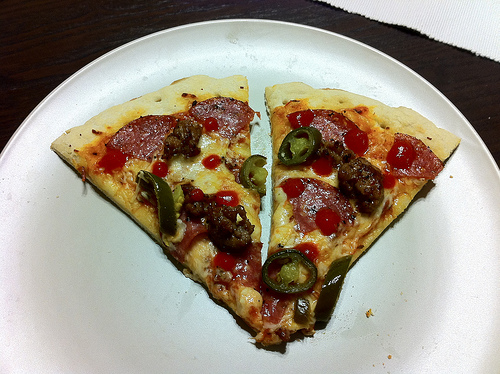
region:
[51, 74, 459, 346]
two slices of pizza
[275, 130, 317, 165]
a jalpeno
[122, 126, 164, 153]
red pepperoni on the pizza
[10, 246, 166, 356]
the pizza pan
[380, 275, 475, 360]
the pizza pan is grey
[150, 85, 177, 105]
the crust on the pizza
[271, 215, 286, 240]
the cheese is yellow on the pizza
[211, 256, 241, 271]
pepperoni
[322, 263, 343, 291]
a green pepper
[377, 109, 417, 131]
the crust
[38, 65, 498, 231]
a plate with two pieces of piza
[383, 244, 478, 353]
the plate is white in color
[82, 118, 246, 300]
the pizza is brown in color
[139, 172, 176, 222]
the peper is green in color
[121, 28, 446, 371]
the plate is half empty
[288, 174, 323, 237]
the tomatoes are red in color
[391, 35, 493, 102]
the table mat is black in color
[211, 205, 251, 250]
the piece of meat is dark brown in color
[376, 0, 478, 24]
the surface is black in color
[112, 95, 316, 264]
the pizza looks deliciuos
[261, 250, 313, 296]
A jalapeno on the pizza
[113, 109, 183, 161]
A slice of pepperoni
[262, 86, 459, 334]
A slice of pizza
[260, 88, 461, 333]
The pizza is shaped like a triangle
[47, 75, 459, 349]
Two pieces of pizza on the plate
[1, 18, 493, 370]
A white plate holding the pizza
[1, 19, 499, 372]
The plate is circular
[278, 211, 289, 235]
Melted cheese on the pizza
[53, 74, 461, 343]
The pizza is cooked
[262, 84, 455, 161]
The crust of the pizza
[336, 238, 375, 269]
part of a pizza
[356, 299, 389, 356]
part of a plate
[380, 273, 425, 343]
part of a palte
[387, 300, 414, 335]
aprt of a plare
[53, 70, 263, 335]
a thin slice of pizza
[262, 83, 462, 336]
a thin slice of pizza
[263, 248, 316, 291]
jalapeno on pizza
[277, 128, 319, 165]
jalapeno on pizza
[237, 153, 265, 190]
jalapeno on pizza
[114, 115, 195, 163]
pepperoni on a pizza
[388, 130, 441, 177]
pepperoni on a pizza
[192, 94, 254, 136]
pepperoni on a pizza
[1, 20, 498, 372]
a white plate has pizza on it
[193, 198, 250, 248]
meat on pizza